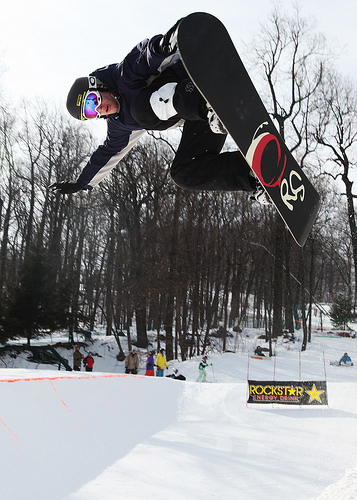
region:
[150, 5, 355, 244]
the snowboard is black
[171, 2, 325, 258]
the snowboard is black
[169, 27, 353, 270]
the snowboard is black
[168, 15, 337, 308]
the snowboard is black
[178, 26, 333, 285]
the snowboard is black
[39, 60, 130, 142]
player is wearing goggles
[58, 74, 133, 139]
player is wearing goggles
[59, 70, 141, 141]
player is wearing goggles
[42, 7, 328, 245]
a person on a snow board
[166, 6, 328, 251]
a red and black snow board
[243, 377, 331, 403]
writing on a black sign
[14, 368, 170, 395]
a orange line on the snow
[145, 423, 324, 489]
a shadow on the snow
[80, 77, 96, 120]
goggles on a persons head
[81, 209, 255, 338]
bare trees in the distance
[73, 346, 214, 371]
fans watching the event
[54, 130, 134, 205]
right arm of snowboarder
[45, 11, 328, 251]
snowboarder and board in the air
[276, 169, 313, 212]
white RS letter print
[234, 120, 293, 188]
white and red design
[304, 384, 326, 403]
yellow star banner design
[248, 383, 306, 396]
yellow print reading Rockstar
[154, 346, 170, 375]
person wearing a yellow coat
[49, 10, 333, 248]
man in the air on his snowboard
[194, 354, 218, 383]
skier on snow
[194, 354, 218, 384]
skier holding a ski pole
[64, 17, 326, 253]
snowboarder in the air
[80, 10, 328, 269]
snowboarder in the air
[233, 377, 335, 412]
banner on the slope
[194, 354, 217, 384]
skier on the slope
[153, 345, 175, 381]
skier on the slope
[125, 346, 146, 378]
skier on the slope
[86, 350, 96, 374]
skier on the slope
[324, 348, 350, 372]
skier on the slope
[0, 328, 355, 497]
A white snow covered ground.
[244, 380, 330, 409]
A red, yellow, and black sign.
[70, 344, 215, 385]
A group of people in multicolored jackets.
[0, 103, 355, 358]
Several leafless trees are in the background.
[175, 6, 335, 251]
The snowboard is black with red and white letters.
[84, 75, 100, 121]
The person is wearing iridescent goggles.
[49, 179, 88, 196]
A black glove covered hand.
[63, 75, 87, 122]
A black hat with a yellow tag on the front.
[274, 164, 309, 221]
RS logo on snowboard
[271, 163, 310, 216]
RS logo on snowboard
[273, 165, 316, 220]
RS logo on snowboard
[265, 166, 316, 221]
RS logo on snowboard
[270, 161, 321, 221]
RS logo on snowboard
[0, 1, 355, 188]
cloud cover in sky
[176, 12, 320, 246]
bottom of airborne snowboard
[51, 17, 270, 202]
sideways man with extended arm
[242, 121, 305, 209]
red and white emblem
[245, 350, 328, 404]
four poles with banner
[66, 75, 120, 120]
helmet on snowboarders head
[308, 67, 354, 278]
tree with no leaves